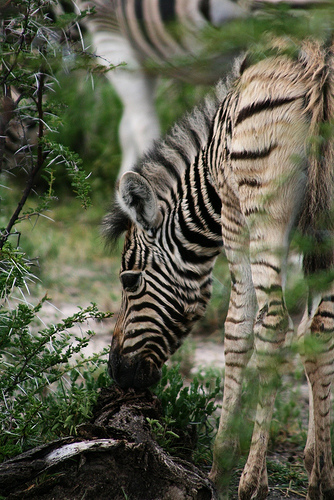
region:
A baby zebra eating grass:
[99, 31, 330, 483]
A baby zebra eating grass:
[100, 25, 323, 473]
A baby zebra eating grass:
[96, 27, 326, 480]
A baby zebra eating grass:
[94, 28, 322, 469]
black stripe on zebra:
[247, 253, 280, 275]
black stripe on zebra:
[242, 200, 267, 218]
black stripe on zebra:
[228, 143, 278, 160]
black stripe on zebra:
[235, 92, 301, 121]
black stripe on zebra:
[223, 359, 243, 369]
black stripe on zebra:
[224, 333, 252, 343]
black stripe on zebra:
[224, 314, 245, 325]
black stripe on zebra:
[124, 310, 176, 350]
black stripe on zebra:
[119, 325, 161, 345]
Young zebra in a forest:
[101, 33, 333, 498]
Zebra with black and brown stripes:
[102, 34, 333, 497]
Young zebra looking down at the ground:
[99, 30, 333, 497]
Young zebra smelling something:
[101, 42, 332, 498]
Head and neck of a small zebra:
[100, 72, 222, 391]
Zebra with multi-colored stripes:
[103, 27, 333, 498]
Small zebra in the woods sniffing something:
[103, 30, 333, 496]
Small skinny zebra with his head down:
[101, 30, 332, 498]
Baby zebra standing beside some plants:
[101, 30, 332, 498]